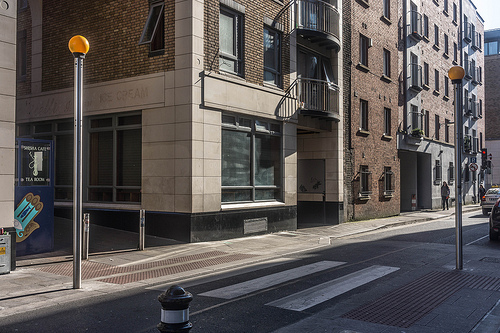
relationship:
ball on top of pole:
[69, 35, 91, 57] [73, 57, 82, 289]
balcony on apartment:
[298, 0, 342, 59] [19, 0, 484, 243]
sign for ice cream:
[17, 71, 165, 123] [98, 86, 148, 107]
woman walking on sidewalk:
[440, 180, 450, 212] [0, 202, 483, 317]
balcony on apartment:
[296, 76, 340, 133] [19, 0, 484, 243]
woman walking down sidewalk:
[440, 180, 450, 212] [0, 202, 483, 317]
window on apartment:
[222, 128, 253, 204] [19, 0, 484, 243]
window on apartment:
[254, 132, 282, 201] [19, 0, 484, 243]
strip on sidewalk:
[15, 248, 229, 281] [0, 202, 483, 317]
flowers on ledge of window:
[412, 128, 425, 140] [411, 103, 418, 132]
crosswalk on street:
[135, 256, 446, 316] [2, 210, 491, 333]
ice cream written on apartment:
[98, 86, 148, 107] [19, 0, 484, 243]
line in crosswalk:
[197, 258, 347, 301] [135, 256, 446, 316]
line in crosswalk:
[265, 264, 401, 312] [135, 256, 446, 316]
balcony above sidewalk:
[298, 0, 342, 59] [0, 202, 483, 317]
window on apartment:
[411, 103, 418, 132] [19, 0, 484, 243]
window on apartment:
[264, 26, 281, 89] [19, 0, 484, 243]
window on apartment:
[219, 9, 242, 74] [19, 0, 484, 243]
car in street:
[482, 187, 499, 214] [2, 210, 491, 333]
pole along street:
[73, 57, 82, 289] [2, 210, 491, 333]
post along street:
[453, 82, 464, 270] [2, 210, 491, 333]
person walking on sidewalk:
[440, 180, 450, 212] [0, 202, 483, 317]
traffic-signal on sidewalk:
[482, 150, 488, 155] [0, 202, 483, 317]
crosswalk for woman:
[135, 256, 446, 316] [440, 180, 450, 212]